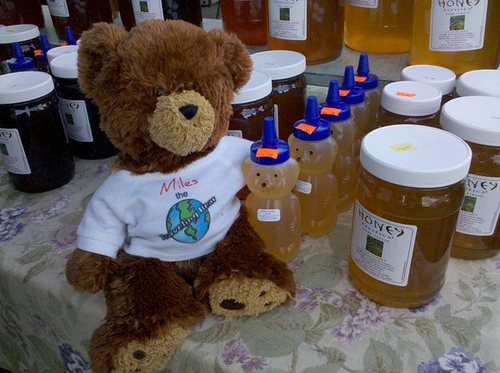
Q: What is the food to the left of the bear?
A: The food is honey.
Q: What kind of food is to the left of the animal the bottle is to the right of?
A: The food is honey.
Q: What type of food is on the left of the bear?
A: The food is honey.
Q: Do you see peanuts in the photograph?
A: No, there are no peanuts.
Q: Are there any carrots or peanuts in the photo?
A: No, there are no peanuts or carrots.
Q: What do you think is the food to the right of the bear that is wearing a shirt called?
A: The food is honey.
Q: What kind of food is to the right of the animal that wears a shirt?
A: The food is honey.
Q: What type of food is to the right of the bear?
A: The food is honey.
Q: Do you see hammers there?
A: No, there are no hammers.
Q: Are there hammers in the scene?
A: No, there are no hammers.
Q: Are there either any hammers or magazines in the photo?
A: No, there are no hammers or magazines.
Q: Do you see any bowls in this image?
A: No, there are no bowls.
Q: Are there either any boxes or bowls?
A: No, there are no bowls or boxes.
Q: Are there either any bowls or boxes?
A: No, there are no bowls or boxes.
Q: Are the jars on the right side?
A: Yes, the jars are on the right of the image.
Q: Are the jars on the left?
A: No, the jars are on the right of the image.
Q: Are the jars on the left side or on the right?
A: The jars are on the right of the image.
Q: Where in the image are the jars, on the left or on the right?
A: The jars are on the right of the image.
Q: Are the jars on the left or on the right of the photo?
A: The jars are on the right of the image.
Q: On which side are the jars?
A: The jars are on the right of the image.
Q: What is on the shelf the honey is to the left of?
A: The jars are on the shelf.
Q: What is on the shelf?
A: The jars are on the shelf.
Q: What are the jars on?
A: The jars are on the shelf.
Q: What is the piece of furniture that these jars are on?
A: The piece of furniture is a shelf.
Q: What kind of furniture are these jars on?
A: The jars are on the shelf.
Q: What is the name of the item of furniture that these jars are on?
A: The piece of furniture is a shelf.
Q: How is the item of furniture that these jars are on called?
A: The piece of furniture is a shelf.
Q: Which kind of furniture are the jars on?
A: The jars are on the shelf.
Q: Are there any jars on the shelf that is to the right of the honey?
A: Yes, there are jars on the shelf.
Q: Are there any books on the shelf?
A: No, there are jars on the shelf.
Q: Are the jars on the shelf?
A: Yes, the jars are on the shelf.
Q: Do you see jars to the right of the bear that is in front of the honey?
A: Yes, there are jars to the right of the bear.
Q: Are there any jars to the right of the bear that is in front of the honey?
A: Yes, there are jars to the right of the bear.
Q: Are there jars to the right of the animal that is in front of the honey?
A: Yes, there are jars to the right of the bear.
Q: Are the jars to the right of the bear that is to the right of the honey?
A: Yes, the jars are to the right of the bear.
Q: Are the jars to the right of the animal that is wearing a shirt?
A: Yes, the jars are to the right of the bear.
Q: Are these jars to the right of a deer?
A: No, the jars are to the right of the bear.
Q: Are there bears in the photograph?
A: Yes, there is a bear.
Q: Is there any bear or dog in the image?
A: Yes, there is a bear.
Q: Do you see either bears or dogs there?
A: Yes, there is a bear.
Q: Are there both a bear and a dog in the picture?
A: No, there is a bear but no dogs.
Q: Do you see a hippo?
A: No, there are no hippoes.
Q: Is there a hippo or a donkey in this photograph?
A: No, there are no hippoes or donkeys.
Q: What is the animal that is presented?
A: The animal is a bear.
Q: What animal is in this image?
A: The animal is a bear.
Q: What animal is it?
A: The animal is a bear.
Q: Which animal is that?
A: That is a bear.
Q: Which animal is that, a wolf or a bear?
A: That is a bear.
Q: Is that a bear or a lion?
A: That is a bear.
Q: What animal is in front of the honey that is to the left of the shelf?
A: The bear is in front of the honey.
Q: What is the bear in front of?
A: The bear is in front of the honey.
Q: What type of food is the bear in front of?
A: The bear is in front of the honey.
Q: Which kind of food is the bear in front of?
A: The bear is in front of the honey.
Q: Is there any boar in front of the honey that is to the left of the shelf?
A: No, there is a bear in front of the honey.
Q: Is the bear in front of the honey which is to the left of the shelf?
A: Yes, the bear is in front of the honey.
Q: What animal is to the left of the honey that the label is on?
A: The animal is a bear.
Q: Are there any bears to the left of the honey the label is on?
A: Yes, there is a bear to the left of the honey.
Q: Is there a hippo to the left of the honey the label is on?
A: No, there is a bear to the left of the honey.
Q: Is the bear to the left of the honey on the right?
A: Yes, the bear is to the left of the honey.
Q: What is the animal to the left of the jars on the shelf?
A: The animal is a bear.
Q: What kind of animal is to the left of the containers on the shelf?
A: The animal is a bear.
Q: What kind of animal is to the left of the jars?
A: The animal is a bear.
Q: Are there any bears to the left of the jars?
A: Yes, there is a bear to the left of the jars.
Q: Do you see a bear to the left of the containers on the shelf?
A: Yes, there is a bear to the left of the jars.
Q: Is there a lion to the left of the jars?
A: No, there is a bear to the left of the jars.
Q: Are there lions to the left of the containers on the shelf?
A: No, there is a bear to the left of the jars.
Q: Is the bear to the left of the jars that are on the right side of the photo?
A: Yes, the bear is to the left of the jars.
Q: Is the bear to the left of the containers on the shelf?
A: Yes, the bear is to the left of the jars.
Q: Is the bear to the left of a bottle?
A: Yes, the bear is to the left of a bottle.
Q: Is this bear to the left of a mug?
A: No, the bear is to the left of a bottle.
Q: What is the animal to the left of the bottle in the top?
A: The animal is a bear.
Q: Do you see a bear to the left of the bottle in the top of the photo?
A: Yes, there is a bear to the left of the bottle.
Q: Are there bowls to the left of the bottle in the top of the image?
A: No, there is a bear to the left of the bottle.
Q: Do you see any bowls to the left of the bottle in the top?
A: No, there is a bear to the left of the bottle.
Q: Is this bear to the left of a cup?
A: No, the bear is to the left of a bottle.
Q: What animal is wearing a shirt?
A: The bear is wearing a shirt.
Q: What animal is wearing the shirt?
A: The bear is wearing a shirt.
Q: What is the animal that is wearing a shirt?
A: The animal is a bear.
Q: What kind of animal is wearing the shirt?
A: The animal is a bear.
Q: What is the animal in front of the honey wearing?
A: The bear is wearing a shirt.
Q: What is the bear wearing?
A: The bear is wearing a shirt.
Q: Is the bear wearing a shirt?
A: Yes, the bear is wearing a shirt.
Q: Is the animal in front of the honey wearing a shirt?
A: Yes, the bear is wearing a shirt.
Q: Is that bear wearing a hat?
A: No, the bear is wearing a shirt.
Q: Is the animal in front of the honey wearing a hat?
A: No, the bear is wearing a shirt.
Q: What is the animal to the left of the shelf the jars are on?
A: The animal is a bear.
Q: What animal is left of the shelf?
A: The animal is a bear.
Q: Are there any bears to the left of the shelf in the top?
A: Yes, there is a bear to the left of the shelf.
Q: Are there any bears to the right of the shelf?
A: No, the bear is to the left of the shelf.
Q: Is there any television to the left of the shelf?
A: No, there is a bear to the left of the shelf.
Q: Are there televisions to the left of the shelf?
A: No, there is a bear to the left of the shelf.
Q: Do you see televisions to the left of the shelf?
A: No, there is a bear to the left of the shelf.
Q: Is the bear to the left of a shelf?
A: Yes, the bear is to the left of a shelf.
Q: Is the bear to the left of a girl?
A: No, the bear is to the left of a shelf.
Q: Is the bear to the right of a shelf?
A: No, the bear is to the left of a shelf.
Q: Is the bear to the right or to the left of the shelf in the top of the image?
A: The bear is to the left of the shelf.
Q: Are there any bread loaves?
A: No, there are no bread loaves.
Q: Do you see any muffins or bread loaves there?
A: No, there are no bread loaves or muffins.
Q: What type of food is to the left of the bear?
A: The food is honey.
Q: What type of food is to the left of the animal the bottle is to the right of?
A: The food is honey.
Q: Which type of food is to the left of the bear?
A: The food is honey.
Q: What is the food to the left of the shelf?
A: The food is honey.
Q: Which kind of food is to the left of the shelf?
A: The food is honey.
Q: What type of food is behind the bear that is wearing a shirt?
A: The food is honey.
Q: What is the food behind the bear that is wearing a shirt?
A: The food is honey.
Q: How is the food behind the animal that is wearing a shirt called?
A: The food is honey.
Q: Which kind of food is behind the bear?
A: The food is honey.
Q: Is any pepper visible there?
A: No, there are no peppers.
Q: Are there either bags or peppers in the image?
A: No, there are no peppers or bags.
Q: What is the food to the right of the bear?
A: The food is honey.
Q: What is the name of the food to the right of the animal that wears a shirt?
A: The food is honey.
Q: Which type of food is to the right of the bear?
A: The food is honey.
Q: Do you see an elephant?
A: No, there are no elephants.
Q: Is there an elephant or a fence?
A: No, there are no elephants or fences.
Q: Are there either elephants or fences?
A: No, there are no elephants or fences.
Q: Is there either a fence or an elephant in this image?
A: No, there are no elephants or fences.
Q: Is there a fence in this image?
A: No, there are no fences.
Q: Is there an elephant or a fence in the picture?
A: No, there are no fences or elephants.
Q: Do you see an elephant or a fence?
A: No, there are no fences or elephants.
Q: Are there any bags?
A: No, there are no bags.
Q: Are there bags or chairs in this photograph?
A: No, there are no bags or chairs.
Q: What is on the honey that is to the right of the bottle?
A: The label is on the honey.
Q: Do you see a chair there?
A: No, there are no chairs.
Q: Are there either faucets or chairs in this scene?
A: No, there are no chairs or faucets.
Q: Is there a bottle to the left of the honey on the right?
A: Yes, there are bottles to the left of the honey.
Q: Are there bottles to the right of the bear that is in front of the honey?
A: Yes, there are bottles to the right of the bear.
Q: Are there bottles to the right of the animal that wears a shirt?
A: Yes, there are bottles to the right of the bear.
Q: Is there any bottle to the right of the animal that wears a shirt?
A: Yes, there are bottles to the right of the bear.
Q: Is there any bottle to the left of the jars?
A: Yes, there are bottles to the left of the jars.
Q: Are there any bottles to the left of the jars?
A: Yes, there are bottles to the left of the jars.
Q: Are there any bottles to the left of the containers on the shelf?
A: Yes, there are bottles to the left of the jars.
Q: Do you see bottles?
A: Yes, there is a bottle.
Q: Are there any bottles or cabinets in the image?
A: Yes, there is a bottle.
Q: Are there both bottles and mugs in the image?
A: No, there is a bottle but no mugs.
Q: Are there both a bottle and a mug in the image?
A: No, there is a bottle but no mugs.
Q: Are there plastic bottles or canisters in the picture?
A: Yes, there is a plastic bottle.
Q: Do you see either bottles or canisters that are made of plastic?
A: Yes, the bottle is made of plastic.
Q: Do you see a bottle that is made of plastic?
A: Yes, there is a bottle that is made of plastic.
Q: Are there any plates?
A: No, there are no plates.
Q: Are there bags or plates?
A: No, there are no plates or bags.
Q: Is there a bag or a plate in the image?
A: No, there are no plates or bags.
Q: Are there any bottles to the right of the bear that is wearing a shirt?
A: Yes, there is a bottle to the right of the bear.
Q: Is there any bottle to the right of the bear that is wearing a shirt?
A: Yes, there is a bottle to the right of the bear.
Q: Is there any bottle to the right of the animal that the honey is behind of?
A: Yes, there is a bottle to the right of the bear.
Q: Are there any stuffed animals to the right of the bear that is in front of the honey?
A: No, there is a bottle to the right of the bear.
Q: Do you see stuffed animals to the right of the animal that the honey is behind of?
A: No, there is a bottle to the right of the bear.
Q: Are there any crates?
A: No, there are no crates.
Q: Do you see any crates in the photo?
A: No, there are no crates.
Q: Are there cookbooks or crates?
A: No, there are no crates or cookbooks.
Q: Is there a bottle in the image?
A: Yes, there is a bottle.